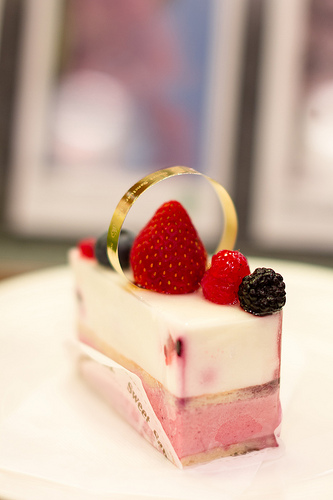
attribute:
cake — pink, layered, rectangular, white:
[68, 165, 285, 467]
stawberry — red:
[130, 200, 209, 293]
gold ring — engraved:
[105, 166, 238, 292]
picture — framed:
[2, 0, 260, 255]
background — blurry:
[0, 1, 332, 498]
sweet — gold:
[124, 380, 153, 426]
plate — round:
[0, 255, 332, 498]